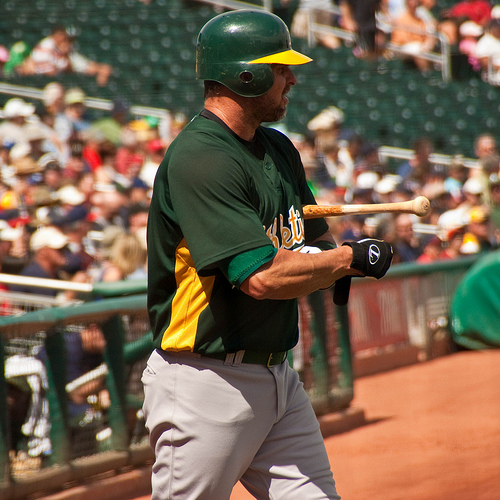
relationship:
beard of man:
[256, 105, 283, 124] [139, 8, 398, 499]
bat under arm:
[280, 179, 494, 227] [212, 240, 347, 317]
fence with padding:
[0, 275, 357, 497] [6, 293, 150, 457]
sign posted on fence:
[350, 280, 426, 354] [6, 279, 359, 496]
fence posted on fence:
[6, 279, 359, 496] [328, 252, 493, 357]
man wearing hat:
[12, 225, 71, 295] [24, 223, 72, 255]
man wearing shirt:
[391, 215, 425, 262] [393, 237, 423, 261]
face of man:
[268, 57, 295, 124] [139, 8, 398, 499]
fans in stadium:
[15, 110, 113, 238] [5, 2, 497, 493]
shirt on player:
[135, 107, 342, 372] [124, 1, 405, 496]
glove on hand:
[340, 239, 405, 282] [340, 237, 396, 283]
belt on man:
[215, 347, 289, 366] [139, 8, 398, 499]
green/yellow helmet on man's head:
[194, 8, 312, 99] [191, 6, 301, 131]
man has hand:
[139, 8, 398, 499] [240, 224, 429, 301]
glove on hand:
[341, 238, 393, 281] [240, 224, 429, 301]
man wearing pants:
[139, 8, 398, 499] [139, 349, 339, 499]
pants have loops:
[139, 349, 339, 499] [199, 332, 252, 372]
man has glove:
[139, 8, 398, 499] [338, 236, 393, 280]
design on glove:
[365, 241, 383, 268] [338, 236, 393, 280]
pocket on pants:
[150, 378, 218, 408] [139, 349, 339, 499]